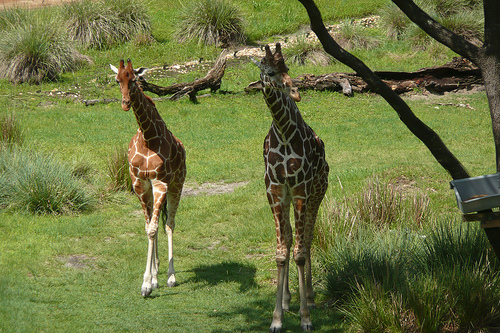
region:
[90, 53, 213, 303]
Giraffe standing in the grass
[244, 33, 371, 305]
Giraffe standing in the grass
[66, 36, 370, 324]
Giraffe standing in the grass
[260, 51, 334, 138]
Giraffe looking straight ahead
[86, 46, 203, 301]
Giraffe standing next to another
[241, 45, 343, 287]
Giraffe standing under a tree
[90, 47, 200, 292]
Giraffe walking in field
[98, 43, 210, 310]
Tall giraffe in a field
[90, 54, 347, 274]
Two giraffes next to each other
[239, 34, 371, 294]
Giraffe under a tree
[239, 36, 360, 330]
Giraffe next to a tree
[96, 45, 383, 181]
Two giraffes looking forward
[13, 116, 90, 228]
Bush of green grass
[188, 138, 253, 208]
Patch of dirt in the field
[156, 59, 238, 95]
Log on the grass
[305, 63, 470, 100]
Log on the grass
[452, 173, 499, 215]
A shallow grey container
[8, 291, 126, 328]
Patch of green grass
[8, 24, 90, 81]
Green bushy spiky shrubs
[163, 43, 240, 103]
A dried up tree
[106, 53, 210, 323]
A young brown giraffe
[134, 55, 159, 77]
A small giraffe ear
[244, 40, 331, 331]
A spotted tall giraffe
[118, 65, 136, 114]
A long narrow face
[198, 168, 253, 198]
Small dried up ground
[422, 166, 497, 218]
White box of feed in tree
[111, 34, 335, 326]
Two giraffes in grass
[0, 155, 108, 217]
Clump of tall grass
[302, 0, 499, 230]
Tree branches with no leaves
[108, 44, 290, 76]
Horns on the giraffes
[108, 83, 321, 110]
Giraffes noses with nostrils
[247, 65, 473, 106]
Bark fallen off dead tree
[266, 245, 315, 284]
Knobby knees on giraffes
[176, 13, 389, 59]
Light dirt area with grass around it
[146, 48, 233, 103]
Dead log on ground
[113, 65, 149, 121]
Giraffe has brown head.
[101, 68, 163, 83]
Giraffe has white ears.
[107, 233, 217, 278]
Bottom of giraffe's legs are white.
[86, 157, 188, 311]
Giraffe is walking in grass.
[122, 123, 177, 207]
Giraffe is brown and white.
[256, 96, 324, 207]
Giraffe is brown and white.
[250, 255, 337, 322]
Bottom of giraffe's legs are white.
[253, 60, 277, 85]
Giraffe has large dark eye.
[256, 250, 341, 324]
Giraffe is standing in grass.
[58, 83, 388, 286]
2 giraffe standing near each other.